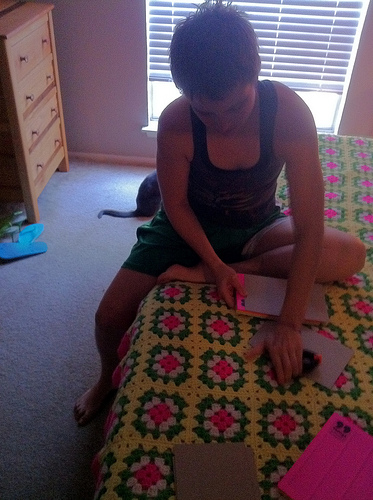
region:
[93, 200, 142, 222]
The tail of the cat on the floor.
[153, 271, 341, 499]
The flowered crocheted blanket on the bed.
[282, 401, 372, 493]
The bright pink paper in the right hand corner.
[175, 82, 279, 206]
The tank top the person is wearing.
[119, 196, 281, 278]
The green shorts the person is wearing.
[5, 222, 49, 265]
The light blue flip flops on the floor.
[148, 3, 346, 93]
The blinds on the window.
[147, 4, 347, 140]
The window behind the person sitting on the bed.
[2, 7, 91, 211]
The wooden dresser in the room.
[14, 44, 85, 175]
The knobs on the drawers of the wooden dresser.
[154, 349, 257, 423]
the blanket has blue squares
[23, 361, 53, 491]
the ground is carpeted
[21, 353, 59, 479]
the floor is grey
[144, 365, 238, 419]
the blacket is yellow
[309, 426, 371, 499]
the object is pink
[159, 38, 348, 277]
the woman is bare foot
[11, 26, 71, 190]
the cabinet is wooden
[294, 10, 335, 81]
the binds are open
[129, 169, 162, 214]
the cat is on the floor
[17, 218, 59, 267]
the slippers are green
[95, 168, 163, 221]
Cat on the ground.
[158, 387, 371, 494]
Stuff on the bed.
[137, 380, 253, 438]
a quilt on the bed.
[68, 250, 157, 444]
A right leg.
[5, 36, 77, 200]
drawers on the dresser.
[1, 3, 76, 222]
The wooden dresser.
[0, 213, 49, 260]
Flip flops on the ground.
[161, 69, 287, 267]
A boy with a tank top.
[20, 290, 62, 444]
the white carpet.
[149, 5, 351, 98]
The glare on the blinds.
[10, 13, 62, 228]
a wooden dresser with four drawers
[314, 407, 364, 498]
a pink piece of paper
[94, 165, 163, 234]
a cat sitting on the floor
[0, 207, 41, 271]
a pair of blue flip flops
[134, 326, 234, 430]
pink, green and yellow bed spread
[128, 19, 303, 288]
a boy sitting on a bed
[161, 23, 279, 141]
a boy with short hair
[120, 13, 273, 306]
a boy wearing green shorts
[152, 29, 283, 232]
a boy wearing a tank top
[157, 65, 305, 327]
a boy holding a tablet of paper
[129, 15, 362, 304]
Boy sitting on bed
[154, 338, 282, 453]
Patterned quilt is pretty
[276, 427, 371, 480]
Pink note paper on bed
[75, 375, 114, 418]
Boy's right foot is white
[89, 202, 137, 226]
Tail of gray cat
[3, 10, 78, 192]
Brown dresser in background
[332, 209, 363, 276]
Boy's left knee is bent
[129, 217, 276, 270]
Child wearing green shorts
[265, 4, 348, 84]
Stacked white blinds near window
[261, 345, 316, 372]
Knuckles of left hand